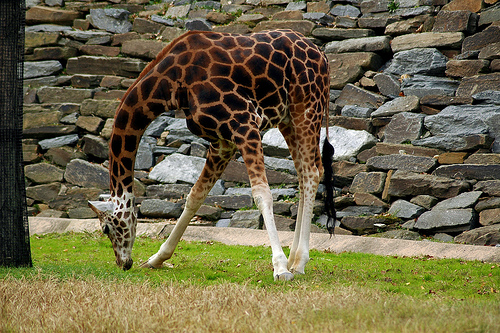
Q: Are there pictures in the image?
A: No, there are no pictures.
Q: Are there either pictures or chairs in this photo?
A: No, there are no pictures or chairs.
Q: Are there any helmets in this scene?
A: No, there are no helmets.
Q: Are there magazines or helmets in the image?
A: No, there are no helmets or magazines.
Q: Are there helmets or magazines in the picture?
A: No, there are no helmets or magazines.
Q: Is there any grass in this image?
A: Yes, there is grass.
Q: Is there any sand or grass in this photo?
A: Yes, there is grass.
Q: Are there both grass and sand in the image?
A: No, there is grass but no sand.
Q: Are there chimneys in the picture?
A: No, there are no chimneys.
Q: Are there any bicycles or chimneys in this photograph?
A: No, there are no chimneys or bicycles.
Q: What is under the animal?
A: The grass is under the animal.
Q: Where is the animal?
A: The animal is on the grass.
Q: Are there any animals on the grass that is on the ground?
A: Yes, there is an animal on the grass.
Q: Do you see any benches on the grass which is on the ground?
A: No, there is an animal on the grass.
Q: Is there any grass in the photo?
A: Yes, there is grass.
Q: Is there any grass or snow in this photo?
A: Yes, there is grass.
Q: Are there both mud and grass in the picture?
A: No, there is grass but no mud.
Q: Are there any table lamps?
A: No, there are no table lamps.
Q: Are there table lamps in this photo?
A: No, there are no table lamps.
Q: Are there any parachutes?
A: No, there are no parachutes.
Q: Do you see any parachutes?
A: No, there are no parachutes.